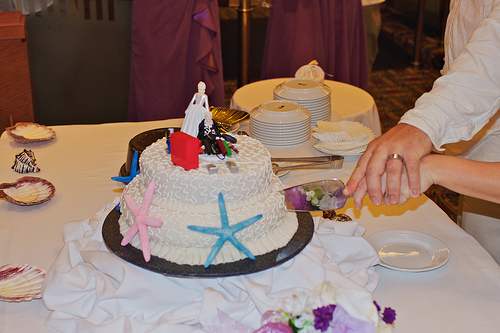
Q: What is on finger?
A: Ring.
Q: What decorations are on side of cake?
A: Stars.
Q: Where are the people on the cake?
A: They are on the top.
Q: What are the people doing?
A: Cutting a cake.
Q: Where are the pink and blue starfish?
A: On the side of the cake.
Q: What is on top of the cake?
A: A bride and groom.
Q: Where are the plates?
A: Right corner of the table.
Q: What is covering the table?
A: A white tablecloth.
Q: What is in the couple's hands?
A: A knife.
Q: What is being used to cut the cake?
A: Knife.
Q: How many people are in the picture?
A: 2.